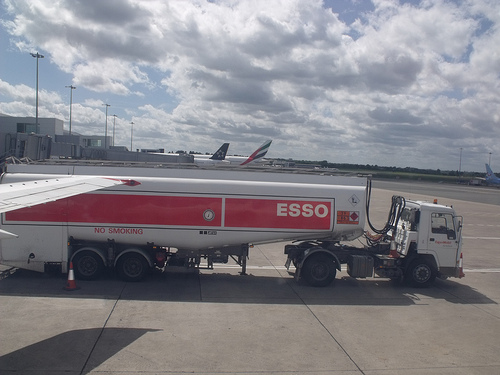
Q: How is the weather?
A: Cloudy.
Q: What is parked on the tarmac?
A: A truck.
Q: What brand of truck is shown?
A: ESSO.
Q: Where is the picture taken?
A: An airport.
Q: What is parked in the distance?
A: Planes.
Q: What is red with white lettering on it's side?
A: Oil truck.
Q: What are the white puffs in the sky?
A: Clouds.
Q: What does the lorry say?
A: Esso.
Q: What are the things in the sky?
A: Clouds.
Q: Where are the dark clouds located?
A: In the middle of the picture.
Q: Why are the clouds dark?
A: Rain.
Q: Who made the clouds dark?
A: Mother nature.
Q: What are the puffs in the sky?
A: Clouds.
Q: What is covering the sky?
A: Clouds.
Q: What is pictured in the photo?
A: Truck.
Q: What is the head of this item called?
A: Truck.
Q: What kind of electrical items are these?
A: Poles.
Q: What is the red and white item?
A: Truck.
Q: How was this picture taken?
A: With a camera.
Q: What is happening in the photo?
A: The truck is parked on a big lot.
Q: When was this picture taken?
A: During daylight.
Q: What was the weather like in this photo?
A: Cloudy.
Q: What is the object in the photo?
A: A semi-truck.